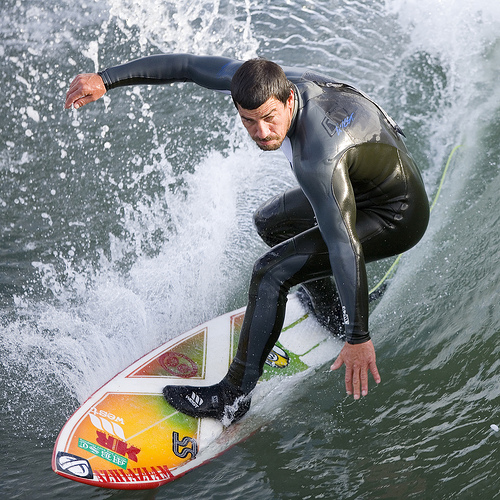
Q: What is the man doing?
A: Surfing.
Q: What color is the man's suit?
A: Black.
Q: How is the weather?
A: Sunny.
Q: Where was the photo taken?
A: On a water body.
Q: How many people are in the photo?
A: One.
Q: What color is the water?
A: Deep blue.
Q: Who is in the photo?
A: A surfer.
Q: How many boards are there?
A: One.